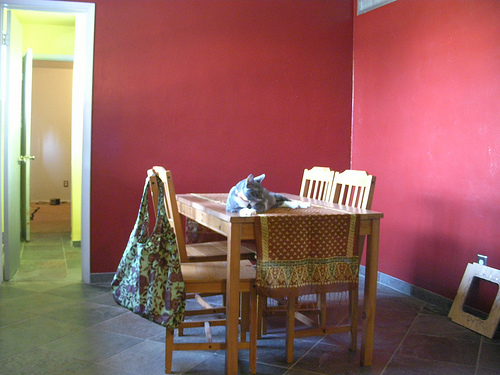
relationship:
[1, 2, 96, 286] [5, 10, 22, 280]
frame of door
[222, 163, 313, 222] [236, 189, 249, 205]
cat with collar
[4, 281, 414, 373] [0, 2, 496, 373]
tile floor in dining room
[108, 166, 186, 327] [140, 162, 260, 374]
bag draped over chair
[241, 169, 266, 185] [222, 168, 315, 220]
ears on cat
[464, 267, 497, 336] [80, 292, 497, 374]
wood on floor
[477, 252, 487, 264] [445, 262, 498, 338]
outlet behind wood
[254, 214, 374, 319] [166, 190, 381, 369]
runner on table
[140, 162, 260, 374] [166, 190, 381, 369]
chair at table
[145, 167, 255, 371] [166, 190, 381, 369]
chair at table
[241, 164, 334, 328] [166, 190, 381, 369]
chair at table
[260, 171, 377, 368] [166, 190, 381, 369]
chair at table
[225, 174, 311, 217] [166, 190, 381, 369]
cat on table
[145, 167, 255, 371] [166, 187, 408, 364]
chair at table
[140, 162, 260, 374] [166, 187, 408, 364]
chair at table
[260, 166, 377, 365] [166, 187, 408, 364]
chair at table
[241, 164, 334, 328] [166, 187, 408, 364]
chair at table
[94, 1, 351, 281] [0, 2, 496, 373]
wall of dining room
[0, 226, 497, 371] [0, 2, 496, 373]
floor of dining room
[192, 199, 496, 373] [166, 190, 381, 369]
shadows of table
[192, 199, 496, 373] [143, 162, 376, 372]
shadows of chairs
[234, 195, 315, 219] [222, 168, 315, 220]
feet of cat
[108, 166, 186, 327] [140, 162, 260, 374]
bag hanging on chair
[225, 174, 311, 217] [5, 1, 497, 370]
cat in dinning room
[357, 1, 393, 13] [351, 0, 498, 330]
vent near wall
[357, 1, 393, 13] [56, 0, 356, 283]
vent near wall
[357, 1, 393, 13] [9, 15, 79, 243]
vent near wall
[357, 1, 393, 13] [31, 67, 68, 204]
vent near wall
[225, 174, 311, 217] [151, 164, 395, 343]
cat on a table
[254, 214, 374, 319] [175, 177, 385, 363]
runner on table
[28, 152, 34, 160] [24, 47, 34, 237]
doorknob on door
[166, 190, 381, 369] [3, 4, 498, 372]
table in room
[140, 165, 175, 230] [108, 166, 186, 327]
strap of bag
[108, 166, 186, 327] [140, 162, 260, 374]
bag on chair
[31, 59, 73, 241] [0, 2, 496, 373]
doorway at end of dining room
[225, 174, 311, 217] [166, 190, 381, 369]
cat on top of table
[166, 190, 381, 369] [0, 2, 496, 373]
table in dining room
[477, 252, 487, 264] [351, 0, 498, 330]
outlet in wall